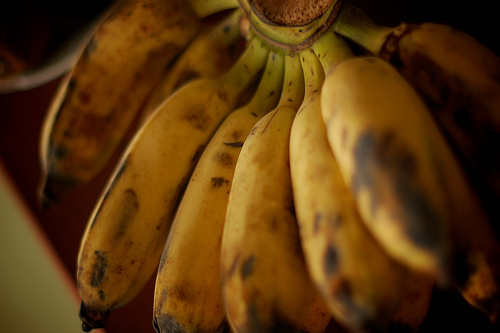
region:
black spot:
[343, 132, 442, 250]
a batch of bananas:
[69, 96, 431, 314]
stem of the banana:
[255, 8, 332, 26]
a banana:
[228, 135, 301, 324]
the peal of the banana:
[229, 162, 301, 316]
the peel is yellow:
[228, 165, 301, 293]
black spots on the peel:
[56, 129, 78, 163]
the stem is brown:
[266, 10, 319, 25]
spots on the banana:
[383, 148, 449, 248]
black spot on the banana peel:
[311, 244, 351, 284]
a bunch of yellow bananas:
[67, 8, 492, 278]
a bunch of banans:
[77, 23, 458, 330]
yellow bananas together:
[76, 14, 499, 303]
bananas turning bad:
[54, 62, 489, 283]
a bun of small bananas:
[77, 26, 489, 264]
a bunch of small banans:
[69, 20, 484, 239]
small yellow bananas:
[54, 56, 492, 250]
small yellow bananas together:
[73, 36, 480, 276]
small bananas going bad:
[87, 59, 494, 311]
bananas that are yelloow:
[49, 66, 495, 306]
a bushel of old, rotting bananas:
[0, 0, 499, 332]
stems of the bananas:
[227, 24, 364, 110]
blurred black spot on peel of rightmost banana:
[335, 115, 461, 260]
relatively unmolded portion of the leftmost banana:
[150, 130, 178, 170]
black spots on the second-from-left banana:
[212, 133, 245, 193]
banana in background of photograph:
[39, 0, 181, 201]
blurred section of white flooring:
[2, 194, 77, 330]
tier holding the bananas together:
[234, 1, 344, 46]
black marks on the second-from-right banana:
[308, 209, 363, 308]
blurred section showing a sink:
[1, 0, 83, 91]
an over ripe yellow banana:
[316, 24, 494, 310]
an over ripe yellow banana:
[291, 44, 427, 331]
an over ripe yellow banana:
[222, 50, 327, 332]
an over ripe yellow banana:
[152, 40, 282, 332]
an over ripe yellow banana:
[37, 0, 235, 205]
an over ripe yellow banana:
[160, 10, 242, 102]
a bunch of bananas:
[36, 2, 499, 332]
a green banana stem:
[222, 35, 268, 90]